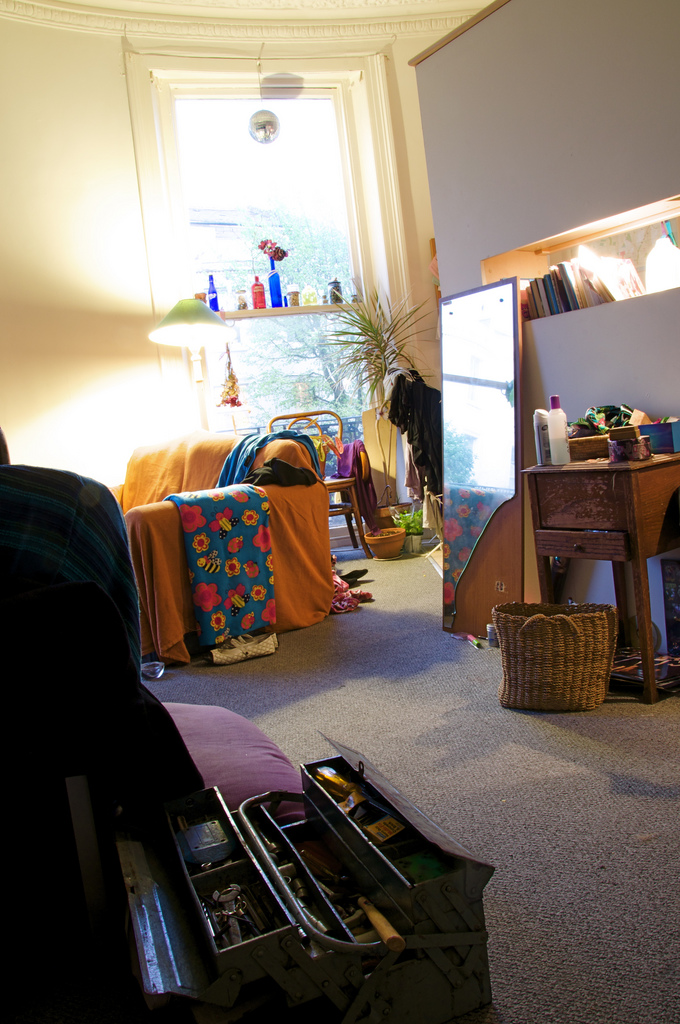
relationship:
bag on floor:
[491, 600, 619, 710] [236, 637, 644, 836]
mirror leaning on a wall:
[439, 276, 525, 638] [414, 25, 658, 632]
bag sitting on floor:
[116, 728, 497, 1024] [382, 705, 657, 1004]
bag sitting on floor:
[491, 600, 619, 710] [367, 678, 658, 846]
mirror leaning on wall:
[439, 276, 525, 638] [429, 45, 657, 644]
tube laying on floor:
[457, 621, 497, 651] [245, 639, 560, 819]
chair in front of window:
[279, 387, 374, 571] [163, 48, 395, 569]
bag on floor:
[453, 558, 627, 703] [484, 730, 653, 864]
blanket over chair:
[158, 464, 336, 672] [77, 411, 384, 658]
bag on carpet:
[116, 728, 497, 1024] [139, 545, 680, 1022]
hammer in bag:
[317, 830, 414, 988] [116, 728, 497, 1024]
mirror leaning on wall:
[409, 257, 596, 761] [421, 229, 575, 709]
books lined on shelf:
[469, 251, 642, 352] [513, 266, 658, 345]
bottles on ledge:
[195, 255, 358, 312] [155, 299, 365, 323]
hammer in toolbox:
[328, 874, 405, 950] [163, 777, 569, 1004]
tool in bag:
[214, 793, 364, 954] [86, 774, 537, 1005]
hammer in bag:
[328, 874, 405, 950] [163, 770, 536, 1022]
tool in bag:
[257, 775, 406, 893] [138, 781, 555, 986]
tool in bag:
[298, 764, 373, 814] [92, 778, 521, 1019]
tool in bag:
[246, 844, 321, 889] [125, 816, 529, 994]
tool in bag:
[248, 849, 325, 907] [144, 759, 540, 1016]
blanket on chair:
[160, 484, 276, 646] [114, 422, 327, 609]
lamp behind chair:
[148, 298, 241, 352] [110, 441, 395, 685]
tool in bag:
[219, 881, 243, 951] [116, 728, 497, 1024]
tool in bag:
[277, 862, 296, 876] [116, 728, 497, 1024]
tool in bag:
[213, 884, 242, 945] [108, 733, 497, 1022]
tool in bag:
[336, 778, 366, 815] [108, 733, 497, 1022]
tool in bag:
[300, 849, 347, 888] [108, 733, 497, 1022]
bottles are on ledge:
[166, 244, 366, 308] [145, 296, 370, 326]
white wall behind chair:
[411, 7, 678, 245] [97, 396, 381, 607]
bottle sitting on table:
[532, 395, 569, 466] [522, 437, 675, 700]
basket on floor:
[475, 595, 629, 713] [136, 593, 677, 1022]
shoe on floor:
[208, 626, 293, 661] [171, 537, 671, 1004]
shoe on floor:
[210, 633, 280, 666] [134, 540, 678, 1016]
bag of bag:
[491, 600, 619, 710] [491, 600, 619, 710]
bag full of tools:
[116, 728, 497, 1024] [166, 755, 467, 966]